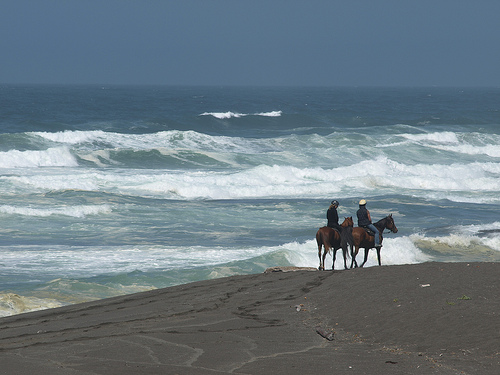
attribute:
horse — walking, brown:
[343, 214, 397, 268]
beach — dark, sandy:
[1, 263, 499, 374]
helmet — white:
[358, 199, 367, 210]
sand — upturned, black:
[1, 261, 498, 373]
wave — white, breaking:
[199, 110, 283, 120]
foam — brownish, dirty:
[416, 239, 499, 261]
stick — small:
[421, 284, 429, 288]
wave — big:
[191, 236, 427, 269]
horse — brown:
[316, 216, 354, 270]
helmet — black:
[331, 199, 338, 207]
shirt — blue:
[357, 209, 373, 226]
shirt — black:
[327, 205, 339, 226]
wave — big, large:
[3, 130, 498, 217]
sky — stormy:
[1, 3, 500, 93]